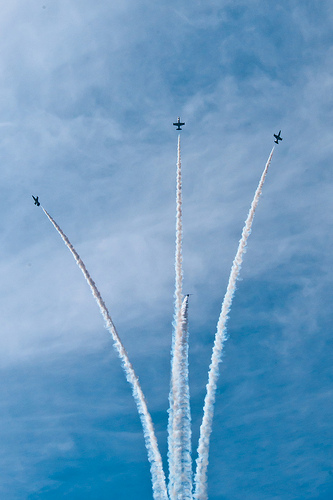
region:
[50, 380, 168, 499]
the sky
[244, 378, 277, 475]
the sky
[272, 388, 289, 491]
the sky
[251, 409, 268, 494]
the sky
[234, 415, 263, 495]
the sky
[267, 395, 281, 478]
the sky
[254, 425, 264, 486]
the sky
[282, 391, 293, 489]
the sky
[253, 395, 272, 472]
the sky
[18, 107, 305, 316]
Four jets in the sky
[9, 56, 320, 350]
The sky is cloudy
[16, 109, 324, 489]
Four aircraft fly in the blue sky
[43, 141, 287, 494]
The jets are leaving thick contrails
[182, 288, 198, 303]
One jet is far below the others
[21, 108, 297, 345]
The airplanes are going in different directions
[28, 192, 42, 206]
The leftmost jet is turning left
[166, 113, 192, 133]
The center jet is flying upwards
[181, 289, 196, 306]
The bottom jet flies toward the camera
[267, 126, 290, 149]
The rightmost jet is banking right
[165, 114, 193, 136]
jet in blue sky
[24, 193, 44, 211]
jet in blue sky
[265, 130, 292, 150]
jet in blue sky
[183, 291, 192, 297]
jet in blue sky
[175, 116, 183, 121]
nose of blue jet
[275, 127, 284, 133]
nose of blue jet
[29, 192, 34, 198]
nose of blue jet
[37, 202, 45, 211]
tail of blue jet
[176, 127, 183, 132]
tail of blue jet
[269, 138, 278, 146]
tail of blue jet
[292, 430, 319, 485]
the sky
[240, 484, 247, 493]
the sky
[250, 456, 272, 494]
the sky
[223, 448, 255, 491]
the sky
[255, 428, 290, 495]
the sky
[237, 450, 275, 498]
the sky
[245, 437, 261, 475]
the sky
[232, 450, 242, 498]
the sky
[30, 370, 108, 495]
the sky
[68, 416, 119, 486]
the sky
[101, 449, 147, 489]
the sky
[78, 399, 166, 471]
the sky